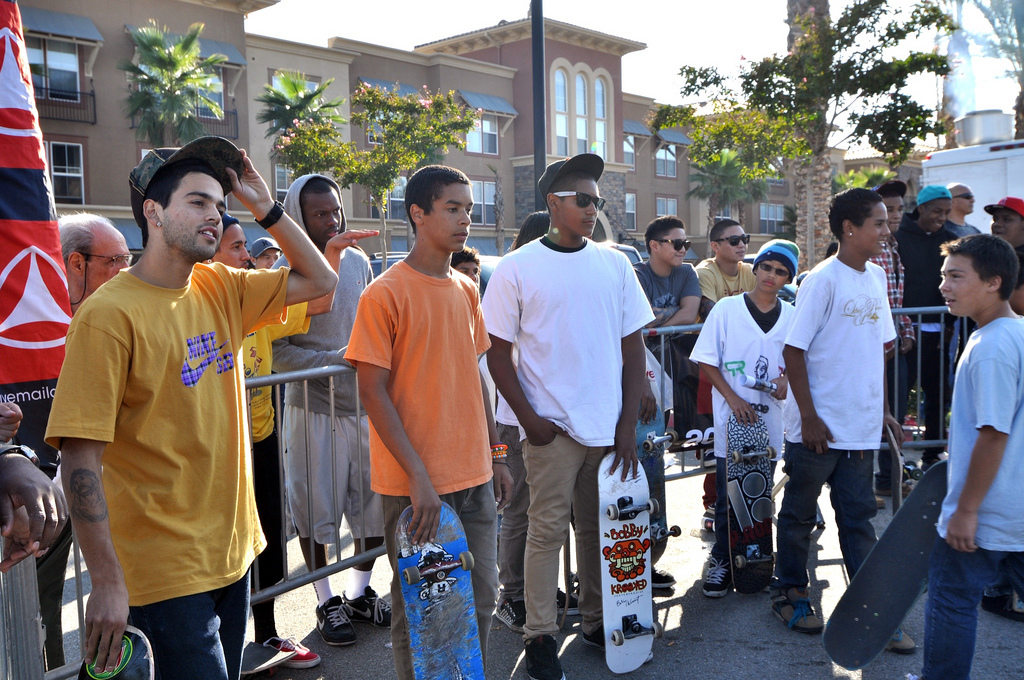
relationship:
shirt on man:
[46, 266, 310, 606] [126, 122, 336, 671]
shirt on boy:
[339, 264, 507, 492] [370, 171, 513, 548]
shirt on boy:
[487, 236, 653, 443] [520, 199, 670, 556]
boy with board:
[927, 232, 1022, 678] [595, 452, 667, 674]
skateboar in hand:
[392, 500, 481, 669] [353, 469, 470, 558]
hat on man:
[118, 134, 243, 207] [87, 186, 316, 632]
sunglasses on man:
[550, 188, 615, 212] [510, 138, 670, 676]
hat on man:
[727, 227, 803, 267] [692, 207, 839, 599]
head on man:
[128, 130, 245, 258] [70, 162, 356, 674]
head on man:
[400, 160, 470, 253] [342, 155, 524, 676]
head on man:
[539, 153, 598, 234] [474, 160, 669, 675]